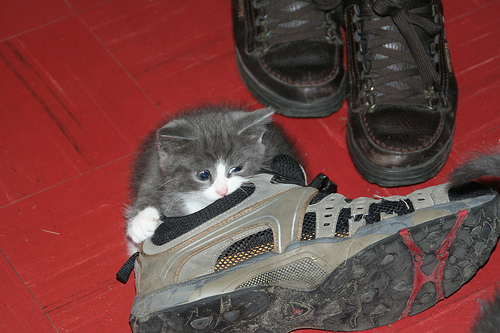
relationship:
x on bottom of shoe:
[391, 211, 468, 322] [132, 176, 497, 330]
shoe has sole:
[132, 176, 497, 330] [132, 203, 498, 333]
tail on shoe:
[444, 148, 499, 180] [132, 176, 497, 330]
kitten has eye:
[125, 102, 309, 246] [192, 158, 215, 187]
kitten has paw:
[125, 102, 309, 246] [129, 207, 159, 242]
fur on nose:
[219, 185, 227, 190] [214, 185, 228, 196]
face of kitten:
[176, 140, 260, 198] [125, 102, 309, 246]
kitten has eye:
[125, 102, 309, 246] [225, 159, 250, 179]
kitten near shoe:
[125, 102, 309, 246] [230, 1, 357, 123]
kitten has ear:
[125, 102, 309, 246] [157, 120, 203, 154]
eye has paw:
[192, 164, 214, 184] [129, 207, 159, 242]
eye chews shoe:
[192, 164, 214, 184] [132, 176, 497, 330]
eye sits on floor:
[192, 164, 214, 184] [2, 1, 499, 332]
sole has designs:
[132, 203, 498, 333] [391, 211, 468, 322]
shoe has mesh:
[132, 176, 497, 330] [217, 224, 275, 274]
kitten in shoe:
[125, 102, 309, 246] [132, 176, 497, 330]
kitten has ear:
[125, 102, 309, 246] [227, 110, 280, 141]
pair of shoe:
[230, 2, 462, 188] [336, 5, 463, 187]